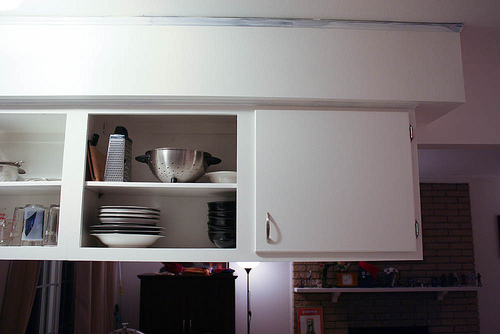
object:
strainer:
[134, 146, 221, 183]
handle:
[265, 213, 271, 243]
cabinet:
[237, 107, 425, 261]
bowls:
[206, 232, 233, 247]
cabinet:
[0, 181, 58, 260]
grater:
[101, 127, 131, 181]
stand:
[245, 267, 252, 334]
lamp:
[244, 265, 256, 269]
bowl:
[205, 171, 236, 184]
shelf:
[85, 181, 235, 188]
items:
[87, 132, 105, 180]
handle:
[136, 154, 149, 163]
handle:
[205, 156, 221, 166]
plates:
[90, 226, 162, 234]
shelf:
[292, 285, 488, 295]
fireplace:
[347, 327, 436, 334]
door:
[253, 110, 417, 254]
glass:
[21, 203, 52, 245]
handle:
[112, 125, 127, 135]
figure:
[476, 272, 483, 286]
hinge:
[409, 123, 415, 141]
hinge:
[414, 221, 420, 238]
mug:
[9, 206, 25, 247]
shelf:
[0, 246, 56, 253]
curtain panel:
[73, 261, 116, 333]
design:
[22, 206, 44, 241]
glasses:
[39, 204, 60, 246]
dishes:
[86, 234, 167, 247]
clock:
[337, 270, 358, 285]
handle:
[187, 319, 194, 331]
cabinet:
[136, 273, 238, 333]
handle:
[179, 318, 187, 328]